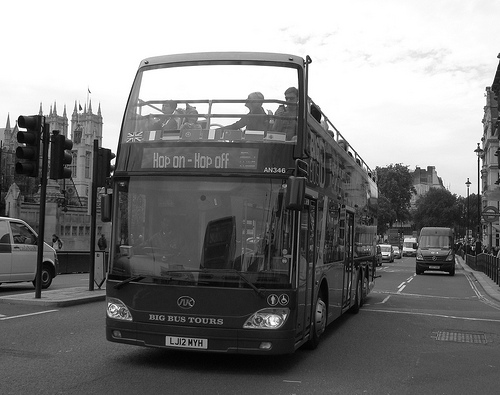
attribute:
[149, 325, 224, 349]
license plate — white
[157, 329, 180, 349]
letters — black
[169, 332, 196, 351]
numbers — black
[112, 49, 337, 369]
bus — black, white, double decker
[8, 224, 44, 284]
van — white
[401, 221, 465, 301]
van — small, dark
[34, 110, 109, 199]
building — light, stone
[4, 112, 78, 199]
traffic lights — dark, metal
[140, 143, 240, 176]
sign — light, lettered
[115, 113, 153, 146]
union jack — black, white